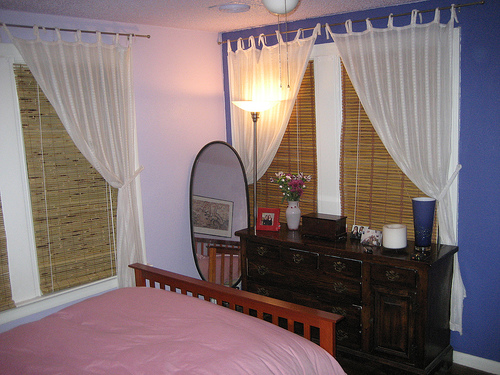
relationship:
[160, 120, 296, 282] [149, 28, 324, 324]
mirror in corner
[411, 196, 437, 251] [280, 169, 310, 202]
cup with flower